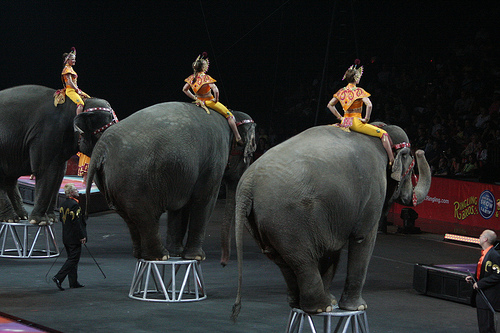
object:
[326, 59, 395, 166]
person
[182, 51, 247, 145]
person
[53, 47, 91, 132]
person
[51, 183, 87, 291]
person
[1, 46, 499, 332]
outdoors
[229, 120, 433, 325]
elephant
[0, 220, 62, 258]
inside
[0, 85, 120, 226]
elephant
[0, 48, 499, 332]
circus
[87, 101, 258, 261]
elephant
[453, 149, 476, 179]
audience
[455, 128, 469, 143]
person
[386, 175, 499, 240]
banner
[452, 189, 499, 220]
sign